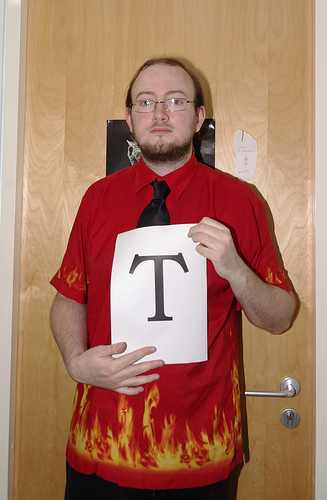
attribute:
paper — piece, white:
[117, 219, 219, 375]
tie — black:
[127, 171, 173, 225]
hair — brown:
[146, 56, 174, 70]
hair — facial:
[139, 143, 180, 168]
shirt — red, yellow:
[76, 180, 243, 425]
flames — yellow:
[68, 398, 244, 478]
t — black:
[132, 250, 189, 331]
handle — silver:
[240, 383, 320, 408]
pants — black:
[65, 459, 249, 498]